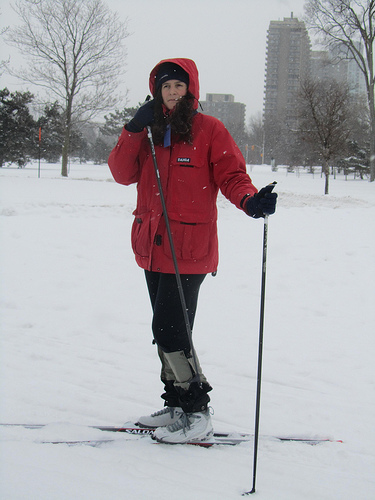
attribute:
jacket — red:
[107, 57, 268, 275]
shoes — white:
[118, 387, 229, 449]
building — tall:
[263, 11, 309, 163]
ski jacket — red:
[108, 54, 254, 274]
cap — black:
[151, 63, 189, 90]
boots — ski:
[120, 340, 293, 465]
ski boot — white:
[147, 415, 220, 449]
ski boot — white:
[132, 407, 177, 427]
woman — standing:
[107, 51, 281, 450]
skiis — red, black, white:
[26, 398, 338, 446]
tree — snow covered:
[33, 97, 97, 185]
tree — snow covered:
[2, 82, 44, 168]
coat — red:
[112, 50, 253, 295]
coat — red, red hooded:
[108, 55, 256, 276]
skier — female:
[93, 45, 279, 448]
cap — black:
[155, 66, 189, 77]